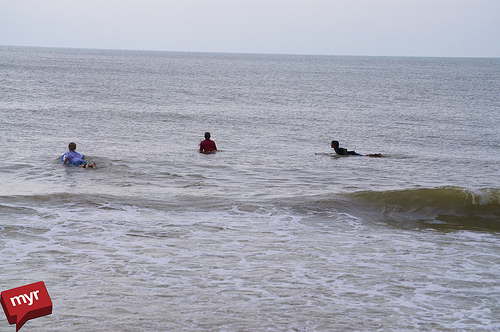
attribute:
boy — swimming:
[57, 138, 97, 170]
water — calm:
[28, 175, 489, 298]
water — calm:
[88, 94, 392, 309]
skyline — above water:
[16, 28, 494, 77]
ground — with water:
[350, 149, 397, 188]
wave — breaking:
[377, 187, 498, 262]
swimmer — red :
[198, 126, 225, 155]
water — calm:
[146, 62, 256, 130]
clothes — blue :
[335, 146, 358, 155]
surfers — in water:
[47, 127, 407, 177]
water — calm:
[2, 44, 498, 325]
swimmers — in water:
[58, 127, 393, 175]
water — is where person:
[128, 198, 324, 279]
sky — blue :
[295, 11, 427, 66]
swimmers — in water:
[57, 131, 404, 168]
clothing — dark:
[334, 148, 374, 158]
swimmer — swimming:
[329, 138, 384, 159]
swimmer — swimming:
[194, 130, 216, 153]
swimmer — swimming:
[57, 139, 99, 169]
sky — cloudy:
[3, 0, 483, 66]